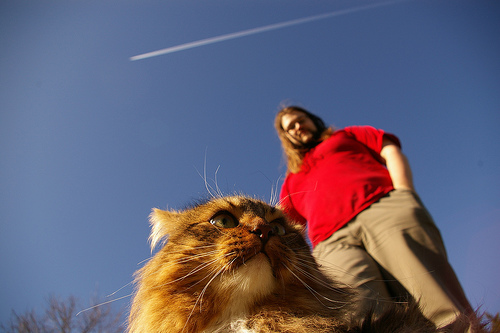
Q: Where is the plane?
A: Sky.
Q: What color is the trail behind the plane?
A: White.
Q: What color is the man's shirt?
A: Red.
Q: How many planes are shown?
A: One.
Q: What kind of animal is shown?
A: Cat.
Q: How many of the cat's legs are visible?
A: None.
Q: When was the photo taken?
A: Daytime.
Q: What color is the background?
A: Blue.